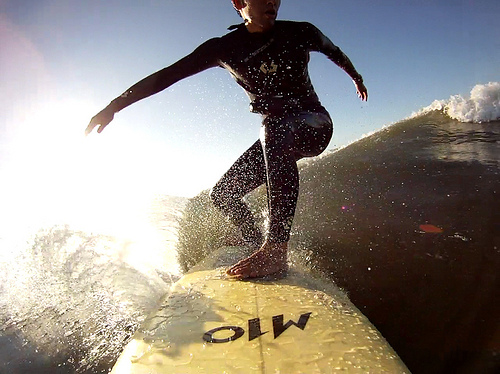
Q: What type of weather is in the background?
A: It is sunny.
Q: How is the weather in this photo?
A: It is sunny.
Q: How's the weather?
A: It is sunny.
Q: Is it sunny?
A: Yes, it is sunny.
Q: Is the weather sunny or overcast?
A: It is sunny.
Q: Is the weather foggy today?
A: No, it is sunny.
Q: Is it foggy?
A: No, it is sunny.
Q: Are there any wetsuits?
A: Yes, there is a wetsuit.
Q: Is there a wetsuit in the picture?
A: Yes, there is a wetsuit.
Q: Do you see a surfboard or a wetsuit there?
A: Yes, there is a wetsuit.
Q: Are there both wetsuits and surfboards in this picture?
A: Yes, there are both a wetsuit and a surfboard.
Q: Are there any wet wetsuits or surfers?
A: Yes, there is a wet wetsuit.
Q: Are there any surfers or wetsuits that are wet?
A: Yes, the wetsuit is wet.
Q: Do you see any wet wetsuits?
A: Yes, there is a wet wetsuit.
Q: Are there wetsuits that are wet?
A: Yes, there is a wetsuit that is wet.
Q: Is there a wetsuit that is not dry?
A: Yes, there is a wet wetsuit.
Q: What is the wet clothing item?
A: The clothing item is a wetsuit.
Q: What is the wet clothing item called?
A: The clothing item is a wetsuit.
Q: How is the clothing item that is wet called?
A: The clothing item is a wetsuit.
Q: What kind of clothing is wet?
A: The clothing is a wetsuit.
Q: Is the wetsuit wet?
A: Yes, the wetsuit is wet.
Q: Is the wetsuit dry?
A: No, the wetsuit is wet.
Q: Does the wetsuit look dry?
A: No, the wetsuit is wet.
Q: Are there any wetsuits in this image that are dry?
A: No, there is a wetsuit but it is wet.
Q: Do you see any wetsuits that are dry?
A: No, there is a wetsuit but it is wet.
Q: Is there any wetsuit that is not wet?
A: No, there is a wetsuit but it is wet.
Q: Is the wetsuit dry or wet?
A: The wetsuit is wet.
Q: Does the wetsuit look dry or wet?
A: The wetsuit is wet.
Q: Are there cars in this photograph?
A: No, there are no cars.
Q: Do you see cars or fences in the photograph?
A: No, there are no cars or fences.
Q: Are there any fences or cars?
A: No, there are no cars or fences.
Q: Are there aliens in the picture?
A: No, there are no aliens.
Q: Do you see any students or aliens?
A: No, there are no aliens or students.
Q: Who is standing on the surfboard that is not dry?
A: The man is standing on the surfboard.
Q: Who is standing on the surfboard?
A: The man is standing on the surfboard.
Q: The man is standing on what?
A: The man is standing on the surfboard.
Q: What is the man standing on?
A: The man is standing on the surfboard.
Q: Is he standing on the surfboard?
A: Yes, the man is standing on the surfboard.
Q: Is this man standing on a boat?
A: No, the man is standing on the surfboard.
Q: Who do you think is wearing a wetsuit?
A: The man is wearing a wetsuit.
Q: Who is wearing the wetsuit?
A: The man is wearing a wetsuit.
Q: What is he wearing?
A: The man is wearing a wet suit.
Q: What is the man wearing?
A: The man is wearing a wet suit.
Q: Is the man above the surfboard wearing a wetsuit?
A: Yes, the man is wearing a wetsuit.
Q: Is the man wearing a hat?
A: No, the man is wearing a wetsuit.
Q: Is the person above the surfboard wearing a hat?
A: No, the man is wearing a wetsuit.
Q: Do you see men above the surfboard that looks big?
A: Yes, there is a man above the surfboard.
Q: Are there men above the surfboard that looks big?
A: Yes, there is a man above the surfboard.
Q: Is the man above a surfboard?
A: Yes, the man is above a surfboard.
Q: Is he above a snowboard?
A: No, the man is above a surfboard.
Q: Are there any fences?
A: No, there are no fences.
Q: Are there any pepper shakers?
A: No, there are no pepper shakers.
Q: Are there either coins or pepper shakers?
A: No, there are no pepper shakers or coins.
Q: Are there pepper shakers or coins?
A: No, there are no pepper shakers or coins.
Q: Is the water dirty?
A: Yes, the water is dirty.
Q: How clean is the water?
A: The water is dirty.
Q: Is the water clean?
A: No, the water is dirty.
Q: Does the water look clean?
A: No, the water is dirty.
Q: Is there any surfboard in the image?
A: Yes, there is a surfboard.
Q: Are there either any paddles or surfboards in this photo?
A: Yes, there is a surfboard.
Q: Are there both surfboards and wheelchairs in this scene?
A: No, there is a surfboard but no wheelchairs.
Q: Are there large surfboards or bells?
A: Yes, there is a large surfboard.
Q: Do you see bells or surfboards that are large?
A: Yes, the surfboard is large.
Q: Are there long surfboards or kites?
A: Yes, there is a long surfboard.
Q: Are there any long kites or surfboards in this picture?
A: Yes, there is a long surfboard.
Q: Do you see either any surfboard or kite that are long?
A: Yes, the surfboard is long.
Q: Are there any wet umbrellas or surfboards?
A: Yes, there is a wet surfboard.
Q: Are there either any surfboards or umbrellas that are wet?
A: Yes, the surfboard is wet.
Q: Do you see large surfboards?
A: Yes, there is a large surfboard.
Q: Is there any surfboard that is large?
A: Yes, there is a surfboard that is large.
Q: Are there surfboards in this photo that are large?
A: Yes, there is a surfboard that is large.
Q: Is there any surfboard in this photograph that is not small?
A: Yes, there is a large surfboard.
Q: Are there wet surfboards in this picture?
A: Yes, there is a wet surfboard.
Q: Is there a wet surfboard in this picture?
A: Yes, there is a wet surfboard.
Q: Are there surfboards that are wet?
A: Yes, there is a surfboard that is wet.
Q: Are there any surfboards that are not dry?
A: Yes, there is a wet surfboard.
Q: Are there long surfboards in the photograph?
A: Yes, there is a long surfboard.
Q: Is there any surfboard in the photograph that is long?
A: Yes, there is a surfboard that is long.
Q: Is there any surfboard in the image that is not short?
A: Yes, there is a long surfboard.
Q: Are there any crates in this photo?
A: No, there are no crates.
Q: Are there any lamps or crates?
A: No, there are no crates or lamps.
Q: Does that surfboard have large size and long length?
A: Yes, the surfboard is large and long.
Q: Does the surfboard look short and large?
A: No, the surfboard is large but long.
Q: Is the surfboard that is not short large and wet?
A: Yes, the surfboard is large and wet.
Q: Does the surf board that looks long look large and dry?
A: No, the surfboard is large but wet.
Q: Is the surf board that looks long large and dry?
A: No, the surfboard is large but wet.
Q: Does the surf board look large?
A: Yes, the surf board is large.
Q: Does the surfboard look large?
A: Yes, the surfboard is large.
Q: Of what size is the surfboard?
A: The surfboard is large.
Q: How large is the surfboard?
A: The surfboard is large.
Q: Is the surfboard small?
A: No, the surfboard is large.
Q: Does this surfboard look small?
A: No, the surfboard is large.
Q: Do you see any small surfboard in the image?
A: No, there is a surfboard but it is large.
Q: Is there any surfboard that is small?
A: No, there is a surfboard but it is large.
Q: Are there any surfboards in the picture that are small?
A: No, there is a surfboard but it is large.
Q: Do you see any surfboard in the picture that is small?
A: No, there is a surfboard but it is large.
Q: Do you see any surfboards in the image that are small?
A: No, there is a surfboard but it is large.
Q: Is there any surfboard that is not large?
A: No, there is a surfboard but it is large.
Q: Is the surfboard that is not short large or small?
A: The surfboard is large.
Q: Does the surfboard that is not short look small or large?
A: The surfboard is large.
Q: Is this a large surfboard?
A: Yes, this is a large surfboard.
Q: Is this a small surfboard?
A: No, this is a large surfboard.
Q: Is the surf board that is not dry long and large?
A: Yes, the surfboard is long and large.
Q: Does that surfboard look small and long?
A: No, the surfboard is long but large.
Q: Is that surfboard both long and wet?
A: Yes, the surfboard is long and wet.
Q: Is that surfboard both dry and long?
A: No, the surfboard is long but wet.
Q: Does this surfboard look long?
A: Yes, the surfboard is long.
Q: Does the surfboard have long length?
A: Yes, the surfboard is long.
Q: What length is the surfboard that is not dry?
A: The surfboard is long.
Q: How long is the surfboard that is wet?
A: The surfboard is long.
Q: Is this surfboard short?
A: No, the surfboard is long.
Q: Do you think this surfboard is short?
A: No, the surfboard is long.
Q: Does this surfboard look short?
A: No, the surfboard is long.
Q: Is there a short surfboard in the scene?
A: No, there is a surfboard but it is long.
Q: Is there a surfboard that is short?
A: No, there is a surfboard but it is long.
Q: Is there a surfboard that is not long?
A: No, there is a surfboard but it is long.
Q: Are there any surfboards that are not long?
A: No, there is a surfboard but it is long.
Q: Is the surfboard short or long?
A: The surfboard is long.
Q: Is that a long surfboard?
A: Yes, that is a long surfboard.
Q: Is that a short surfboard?
A: No, that is a long surfboard.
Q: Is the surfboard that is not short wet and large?
A: Yes, the surfboard is wet and large.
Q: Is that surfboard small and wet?
A: No, the surfboard is wet but large.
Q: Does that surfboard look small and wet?
A: No, the surfboard is wet but large.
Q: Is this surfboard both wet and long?
A: Yes, the surfboard is wet and long.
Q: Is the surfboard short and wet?
A: No, the surfboard is wet but long.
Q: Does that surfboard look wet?
A: Yes, the surfboard is wet.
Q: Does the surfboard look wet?
A: Yes, the surfboard is wet.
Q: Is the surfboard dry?
A: No, the surfboard is wet.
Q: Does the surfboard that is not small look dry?
A: No, the surfboard is wet.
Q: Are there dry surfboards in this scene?
A: No, there is a surfboard but it is wet.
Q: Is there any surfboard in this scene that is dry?
A: No, there is a surfboard but it is wet.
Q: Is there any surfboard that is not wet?
A: No, there is a surfboard but it is wet.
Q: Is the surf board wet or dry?
A: The surf board is wet.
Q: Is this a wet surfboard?
A: Yes, this is a wet surfboard.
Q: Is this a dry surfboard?
A: No, this is a wet surfboard.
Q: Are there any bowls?
A: No, there are no bowls.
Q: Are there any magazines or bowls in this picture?
A: No, there are no bowls or magazines.